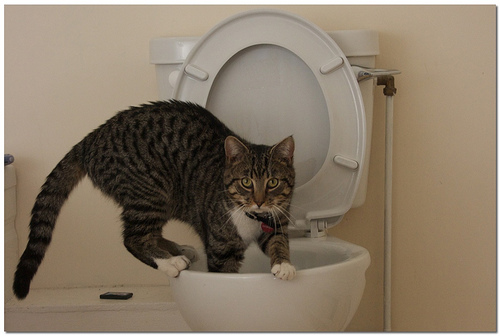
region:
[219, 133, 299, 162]
ears of a cat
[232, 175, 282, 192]
green eyes of a cat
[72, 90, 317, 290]
cat with green eyes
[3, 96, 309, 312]
grey cat with white paws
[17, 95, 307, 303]
cat standing on a toilet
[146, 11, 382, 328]
white ceramic toilet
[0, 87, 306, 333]
grey cat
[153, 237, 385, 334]
white toilet bowl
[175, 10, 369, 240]
seat of a toilet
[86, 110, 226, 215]
black stripes on a cat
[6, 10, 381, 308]
a cat standing on a toilet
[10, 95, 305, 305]
a silver and black cat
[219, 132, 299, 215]
the head of a cat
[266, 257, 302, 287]
the paw of a cat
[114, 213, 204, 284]
the rear legs of a cat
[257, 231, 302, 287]
the front leg of a cat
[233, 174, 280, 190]
the eyes of a cat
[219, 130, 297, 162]
the ears of a cat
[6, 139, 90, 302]
the tail of a cat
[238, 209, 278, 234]
the collar of a cat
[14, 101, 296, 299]
A cat on the toilet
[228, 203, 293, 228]
The whiskers of the cat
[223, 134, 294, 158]
The ears of the cat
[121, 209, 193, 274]
The back legs of the cat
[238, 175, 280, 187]
The eyes of the cat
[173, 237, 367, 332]
The bowl of the toilet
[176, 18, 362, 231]
The seat of the toilet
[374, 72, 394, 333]
A pipe connected to the toilet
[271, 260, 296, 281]
The front paw of the cat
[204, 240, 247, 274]
The cat has a leg in the toilet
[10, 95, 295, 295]
Cat standing on an open toilet.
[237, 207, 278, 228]
Cat wearing a black collar.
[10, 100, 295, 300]
Cat with black and brown coat.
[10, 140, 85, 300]
Cat has long tail.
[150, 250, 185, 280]
Cat has white paws.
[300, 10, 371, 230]
Toilet seat is up.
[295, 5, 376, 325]
Toilet is off white.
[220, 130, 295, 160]
Cat's ears are pointing up.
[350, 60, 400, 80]
Toilet handle is silver.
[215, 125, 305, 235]
Cat looking at the photographer.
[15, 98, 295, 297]
the cat standing on the toilet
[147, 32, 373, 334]
the white toilet the kitty is standing on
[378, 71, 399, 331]
the pipe next to the toilet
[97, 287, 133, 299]
a piece of black plastic on the counter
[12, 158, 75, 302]
the tail of the kitty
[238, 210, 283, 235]
the collar on the cat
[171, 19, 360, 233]
the lid of the toilet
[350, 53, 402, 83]
the handle on the toilet tank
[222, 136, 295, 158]
the ears of the cat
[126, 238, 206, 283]
the back paws of the kitty